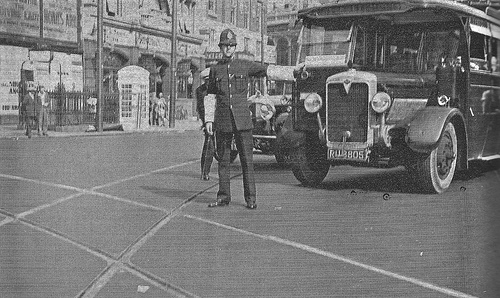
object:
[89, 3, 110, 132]
pole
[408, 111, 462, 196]
wheel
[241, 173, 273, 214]
shoe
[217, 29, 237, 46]
hat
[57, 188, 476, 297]
lines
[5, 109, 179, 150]
sidewalk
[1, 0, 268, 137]
building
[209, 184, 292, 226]
shoes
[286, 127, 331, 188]
wheels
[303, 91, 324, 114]
lights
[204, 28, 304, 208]
man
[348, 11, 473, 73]
windows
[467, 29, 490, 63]
windows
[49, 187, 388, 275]
street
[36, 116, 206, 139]
sidewalk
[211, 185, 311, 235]
shoes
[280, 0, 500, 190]
bus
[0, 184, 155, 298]
lines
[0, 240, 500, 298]
road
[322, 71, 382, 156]
grill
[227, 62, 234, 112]
buttons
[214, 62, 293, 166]
car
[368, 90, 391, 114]
lights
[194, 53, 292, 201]
uniform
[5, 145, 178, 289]
street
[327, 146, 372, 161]
license plate